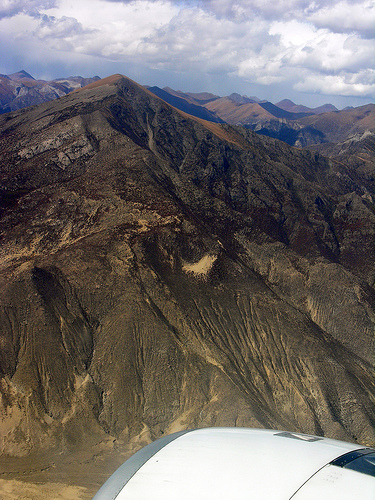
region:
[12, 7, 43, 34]
white clouds in blue sky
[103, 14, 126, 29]
white clouds in blue sky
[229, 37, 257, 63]
white clouds in blue sky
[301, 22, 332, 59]
white clouds in blue sky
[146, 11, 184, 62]
white clouds in blue sky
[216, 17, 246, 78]
white clouds in blue sky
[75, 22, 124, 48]
white clouds in blue sky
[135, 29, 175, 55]
white clouds in blue sky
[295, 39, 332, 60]
white clouds in blue sky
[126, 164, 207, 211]
brown side of mountain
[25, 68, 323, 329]
large mountains in the area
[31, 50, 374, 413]
an area with large mountains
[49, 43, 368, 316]
a mountain taht is brown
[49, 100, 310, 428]
mountains without trees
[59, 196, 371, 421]
mountains without grass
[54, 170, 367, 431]
large mountains without trees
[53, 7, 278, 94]
a blue cloudy sky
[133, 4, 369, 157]
a blue sky that is cloudy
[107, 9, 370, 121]
a sky that is blue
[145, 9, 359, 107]
a cloudy sky that is blue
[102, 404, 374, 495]
engine of a jet engine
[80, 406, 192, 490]
black edge of the engine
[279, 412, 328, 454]
black number on the engine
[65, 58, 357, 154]
mountain peaks are brown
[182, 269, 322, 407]
lines and grooves down the mountain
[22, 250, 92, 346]
shaded area of the mountain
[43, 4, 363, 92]
many clouds in the sky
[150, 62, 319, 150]
mountains are different colors and shades of brown yellow and grey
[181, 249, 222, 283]
light tan area on the mountain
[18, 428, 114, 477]
valley of the mountain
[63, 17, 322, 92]
the clouds are big and gray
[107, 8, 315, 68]
the clouds are big and gray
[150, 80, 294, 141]
mountains in the distance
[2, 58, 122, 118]
mountains in the distance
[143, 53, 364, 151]
mountains in the distance